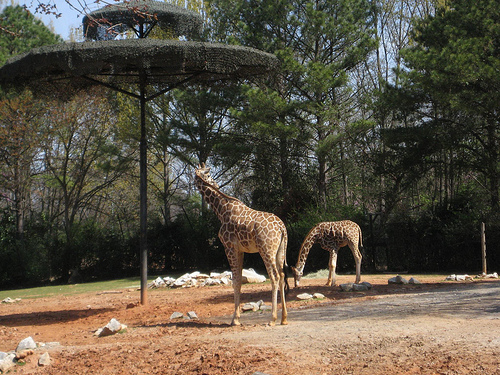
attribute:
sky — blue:
[43, 0, 84, 30]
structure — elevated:
[10, 20, 274, 74]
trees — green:
[17, 78, 139, 294]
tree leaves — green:
[350, 1, 498, 189]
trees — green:
[1, 1, 499, 273]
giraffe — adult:
[188, 163, 295, 329]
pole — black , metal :
[131, 86, 156, 303]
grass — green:
[64, 241, 121, 304]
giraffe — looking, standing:
[173, 143, 315, 349]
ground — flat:
[3, 273, 500, 375]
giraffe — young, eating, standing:
[277, 204, 374, 305]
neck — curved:
[189, 174, 238, 220]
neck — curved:
[295, 223, 321, 273]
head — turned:
[181, 157, 226, 199]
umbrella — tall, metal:
[0, 2, 275, 312]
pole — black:
[126, 76, 161, 312]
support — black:
[145, 71, 205, 111]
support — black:
[76, 76, 140, 107]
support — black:
[121, 16, 167, 41]